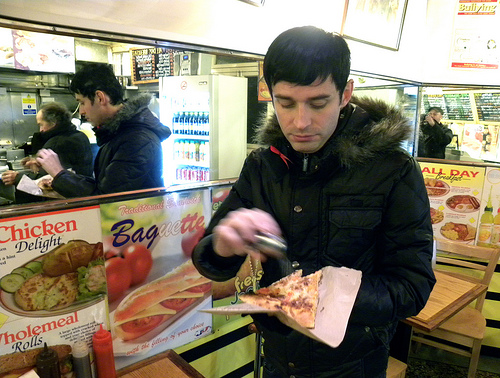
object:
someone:
[188, 22, 434, 377]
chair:
[432, 237, 498, 377]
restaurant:
[0, 2, 499, 377]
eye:
[272, 99, 295, 106]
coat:
[229, 141, 423, 303]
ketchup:
[92, 347, 114, 376]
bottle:
[91, 323, 113, 374]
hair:
[262, 30, 345, 85]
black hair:
[264, 25, 349, 80]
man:
[37, 66, 167, 192]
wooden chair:
[401, 238, 498, 375]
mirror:
[48, 47, 97, 65]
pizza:
[256, 271, 328, 318]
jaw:
[286, 141, 329, 155]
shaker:
[254, 230, 293, 265]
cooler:
[155, 72, 240, 180]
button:
[289, 201, 303, 218]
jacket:
[231, 118, 413, 339]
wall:
[0, 177, 200, 375]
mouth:
[286, 129, 323, 142]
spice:
[247, 227, 289, 253]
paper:
[331, 278, 350, 314]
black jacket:
[247, 150, 435, 376]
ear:
[334, 79, 356, 106]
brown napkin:
[14, 172, 70, 199]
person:
[255, 24, 415, 353]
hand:
[199, 204, 301, 260]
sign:
[1, 203, 110, 355]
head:
[261, 22, 354, 154]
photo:
[105, 246, 157, 288]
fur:
[347, 98, 401, 143]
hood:
[336, 110, 356, 139]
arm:
[373, 178, 434, 329]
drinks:
[170, 98, 209, 177]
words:
[0, 216, 83, 256]